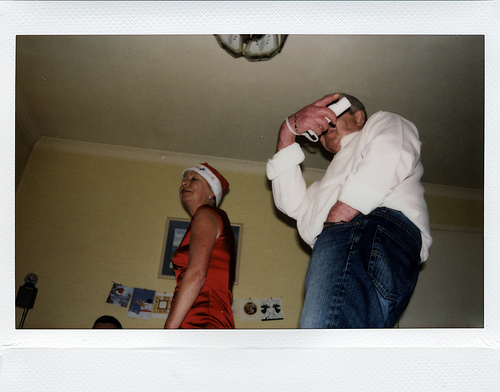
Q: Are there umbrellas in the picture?
A: No, there are no umbrellas.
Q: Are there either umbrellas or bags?
A: No, there are no umbrellas or bags.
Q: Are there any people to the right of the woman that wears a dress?
A: Yes, there are people to the right of the woman.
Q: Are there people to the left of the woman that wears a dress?
A: No, the people are to the right of the woman.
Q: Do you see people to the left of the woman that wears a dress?
A: No, the people are to the right of the woman.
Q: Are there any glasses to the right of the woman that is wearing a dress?
A: No, there are people to the right of the woman.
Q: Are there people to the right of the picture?
A: Yes, there are people to the right of the picture.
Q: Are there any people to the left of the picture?
A: No, the people are to the right of the picture.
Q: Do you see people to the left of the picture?
A: No, the people are to the right of the picture.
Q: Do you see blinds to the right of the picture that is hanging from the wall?
A: No, there are people to the right of the picture.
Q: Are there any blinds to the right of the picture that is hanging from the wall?
A: No, there are people to the right of the picture.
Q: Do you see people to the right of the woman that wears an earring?
A: Yes, there are people to the right of the woman.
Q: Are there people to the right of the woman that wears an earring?
A: Yes, there are people to the right of the woman.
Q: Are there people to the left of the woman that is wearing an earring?
A: No, the people are to the right of the woman.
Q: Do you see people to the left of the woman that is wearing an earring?
A: No, the people are to the right of the woman.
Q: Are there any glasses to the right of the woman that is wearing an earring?
A: No, there are people to the right of the woman.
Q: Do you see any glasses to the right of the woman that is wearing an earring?
A: No, there are people to the right of the woman.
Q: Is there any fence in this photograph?
A: No, there are no fences.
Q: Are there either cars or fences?
A: No, there are no fences or cars.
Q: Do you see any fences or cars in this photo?
A: No, there are no fences or cars.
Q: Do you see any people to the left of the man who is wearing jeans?
A: Yes, there are people to the left of the man.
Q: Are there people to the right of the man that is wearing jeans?
A: No, the people are to the left of the man.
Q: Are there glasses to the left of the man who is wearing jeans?
A: No, there are people to the left of the man.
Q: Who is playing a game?
A: The people are playing a game.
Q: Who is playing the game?
A: The people are playing a game.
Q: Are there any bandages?
A: No, there are no bandages.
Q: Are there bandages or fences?
A: No, there are no bandages or fences.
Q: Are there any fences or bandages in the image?
A: No, there are no bandages or fences.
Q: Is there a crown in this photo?
A: No, there are no crowns.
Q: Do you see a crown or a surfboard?
A: No, there are no crowns or surfboards.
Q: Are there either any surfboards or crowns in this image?
A: No, there are no crowns or surfboards.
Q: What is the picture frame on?
A: The picture frame is on the wall.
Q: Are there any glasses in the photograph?
A: No, there are no glasses.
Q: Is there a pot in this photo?
A: No, there are no pots.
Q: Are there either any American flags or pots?
A: No, there are no pots or American flags.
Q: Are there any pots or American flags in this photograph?
A: No, there are no pots or American flags.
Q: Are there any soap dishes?
A: No, there are no soap dishes.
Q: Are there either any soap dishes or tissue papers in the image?
A: No, there are no soap dishes or tissue papers.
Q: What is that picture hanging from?
A: The picture is hanging from the wall.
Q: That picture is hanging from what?
A: The picture is hanging from the wall.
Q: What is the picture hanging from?
A: The picture is hanging from the wall.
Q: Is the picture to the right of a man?
A: No, the picture is to the left of a man.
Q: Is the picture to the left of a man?
A: Yes, the picture is to the left of a man.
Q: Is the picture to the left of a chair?
A: No, the picture is to the left of a man.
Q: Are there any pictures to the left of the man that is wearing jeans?
A: Yes, there is a picture to the left of the man.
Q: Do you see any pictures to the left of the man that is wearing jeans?
A: Yes, there is a picture to the left of the man.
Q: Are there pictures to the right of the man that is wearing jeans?
A: No, the picture is to the left of the man.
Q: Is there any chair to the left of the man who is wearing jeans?
A: No, there is a picture to the left of the man.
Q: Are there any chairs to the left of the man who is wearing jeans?
A: No, there is a picture to the left of the man.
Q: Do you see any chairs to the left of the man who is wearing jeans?
A: No, there is a picture to the left of the man.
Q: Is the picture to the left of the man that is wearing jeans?
A: Yes, the picture is to the left of the man.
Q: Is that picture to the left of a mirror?
A: No, the picture is to the left of the man.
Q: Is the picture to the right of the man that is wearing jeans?
A: No, the picture is to the left of the man.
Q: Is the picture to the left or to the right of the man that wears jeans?
A: The picture is to the left of the man.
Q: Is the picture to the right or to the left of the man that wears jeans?
A: The picture is to the left of the man.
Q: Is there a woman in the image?
A: Yes, there is a woman.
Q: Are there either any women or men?
A: Yes, there is a woman.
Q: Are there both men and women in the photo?
A: Yes, there are both a woman and a man.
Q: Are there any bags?
A: No, there are no bags.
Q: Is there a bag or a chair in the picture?
A: No, there are no bags or chairs.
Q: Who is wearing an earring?
A: The woman is wearing an earring.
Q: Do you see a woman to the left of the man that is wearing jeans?
A: Yes, there is a woman to the left of the man.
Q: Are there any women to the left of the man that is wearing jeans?
A: Yes, there is a woman to the left of the man.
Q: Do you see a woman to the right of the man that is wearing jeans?
A: No, the woman is to the left of the man.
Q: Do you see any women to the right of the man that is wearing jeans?
A: No, the woman is to the left of the man.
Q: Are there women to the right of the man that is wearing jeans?
A: No, the woman is to the left of the man.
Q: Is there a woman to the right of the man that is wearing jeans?
A: No, the woman is to the left of the man.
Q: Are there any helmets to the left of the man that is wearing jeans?
A: No, there is a woman to the left of the man.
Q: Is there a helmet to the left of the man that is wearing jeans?
A: No, there is a woman to the left of the man.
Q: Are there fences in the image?
A: No, there are no fences.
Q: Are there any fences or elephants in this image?
A: No, there are no fences or elephants.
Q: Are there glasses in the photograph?
A: No, there are no glasses.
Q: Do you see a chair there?
A: No, there are no chairs.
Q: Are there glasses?
A: No, there are no glasses.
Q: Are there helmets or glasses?
A: No, there are no glasses or helmets.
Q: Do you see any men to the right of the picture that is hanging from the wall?
A: Yes, there is a man to the right of the picture.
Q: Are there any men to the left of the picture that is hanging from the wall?
A: No, the man is to the right of the picture.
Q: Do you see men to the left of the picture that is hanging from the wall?
A: No, the man is to the right of the picture.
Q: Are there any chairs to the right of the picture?
A: No, there is a man to the right of the picture.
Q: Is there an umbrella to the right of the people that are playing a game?
A: No, there is a man to the right of the people.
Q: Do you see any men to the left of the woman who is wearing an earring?
A: No, the man is to the right of the woman.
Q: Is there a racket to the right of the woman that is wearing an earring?
A: No, there is a man to the right of the woman.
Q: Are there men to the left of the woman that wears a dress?
A: No, the man is to the right of the woman.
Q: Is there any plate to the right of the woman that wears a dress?
A: No, there is a man to the right of the woman.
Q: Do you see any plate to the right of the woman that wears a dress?
A: No, there is a man to the right of the woman.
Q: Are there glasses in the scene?
A: No, there are no glasses.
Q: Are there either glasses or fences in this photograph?
A: No, there are no glasses or fences.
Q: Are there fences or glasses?
A: No, there are no glasses or fences.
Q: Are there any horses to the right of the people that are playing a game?
A: No, there is a man to the right of the people.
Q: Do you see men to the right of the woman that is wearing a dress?
A: Yes, there is a man to the right of the woman.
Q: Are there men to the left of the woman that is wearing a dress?
A: No, the man is to the right of the woman.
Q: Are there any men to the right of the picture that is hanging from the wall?
A: Yes, there is a man to the right of the picture.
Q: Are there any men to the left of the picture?
A: No, the man is to the right of the picture.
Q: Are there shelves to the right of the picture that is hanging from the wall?
A: No, there is a man to the right of the picture.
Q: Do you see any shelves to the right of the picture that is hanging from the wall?
A: No, there is a man to the right of the picture.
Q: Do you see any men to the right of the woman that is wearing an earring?
A: Yes, there is a man to the right of the woman.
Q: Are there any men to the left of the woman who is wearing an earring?
A: No, the man is to the right of the woman.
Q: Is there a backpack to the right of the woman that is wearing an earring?
A: No, there is a man to the right of the woman.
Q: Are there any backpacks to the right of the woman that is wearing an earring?
A: No, there is a man to the right of the woman.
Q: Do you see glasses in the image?
A: No, there are no glasses.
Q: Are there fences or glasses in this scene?
A: No, there are no glasses or fences.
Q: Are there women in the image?
A: Yes, there is a woman.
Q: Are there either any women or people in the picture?
A: Yes, there is a woman.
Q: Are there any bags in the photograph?
A: No, there are no bags.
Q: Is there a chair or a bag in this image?
A: No, there are no bags or chairs.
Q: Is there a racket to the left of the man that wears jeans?
A: No, there is a woman to the left of the man.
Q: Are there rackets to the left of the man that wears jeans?
A: No, there is a woman to the left of the man.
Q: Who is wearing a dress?
A: The woman is wearing a dress.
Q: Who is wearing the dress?
A: The woman is wearing a dress.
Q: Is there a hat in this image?
A: Yes, there is a hat.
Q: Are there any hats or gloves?
A: Yes, there is a hat.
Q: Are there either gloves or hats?
A: Yes, there is a hat.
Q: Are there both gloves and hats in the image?
A: No, there is a hat but no gloves.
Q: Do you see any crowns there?
A: No, there are no crowns.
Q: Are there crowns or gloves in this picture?
A: No, there are no crowns or gloves.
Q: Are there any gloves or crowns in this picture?
A: No, there are no crowns or gloves.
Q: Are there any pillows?
A: No, there are no pillows.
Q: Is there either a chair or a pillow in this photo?
A: No, there are no pillows or chairs.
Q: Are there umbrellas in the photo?
A: No, there are no umbrellas.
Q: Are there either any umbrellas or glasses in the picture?
A: No, there are no umbrellas or glasses.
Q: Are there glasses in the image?
A: No, there are no glasses.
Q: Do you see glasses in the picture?
A: No, there are no glasses.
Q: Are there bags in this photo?
A: No, there are no bags.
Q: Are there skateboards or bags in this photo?
A: No, there are no bags or skateboards.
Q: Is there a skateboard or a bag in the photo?
A: No, there are no bags or skateboards.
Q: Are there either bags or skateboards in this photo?
A: No, there are no bags or skateboards.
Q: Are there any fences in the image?
A: No, there are no fences.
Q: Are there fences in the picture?
A: No, there are no fences.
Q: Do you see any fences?
A: No, there are no fences.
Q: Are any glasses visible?
A: No, there are no glasses.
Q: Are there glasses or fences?
A: No, there are no glasses or fences.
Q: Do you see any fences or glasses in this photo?
A: No, there are no glasses or fences.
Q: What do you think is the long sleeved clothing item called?
A: The clothing item is a shirt.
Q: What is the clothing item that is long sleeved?
A: The clothing item is a shirt.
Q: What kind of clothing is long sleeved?
A: The clothing is a shirt.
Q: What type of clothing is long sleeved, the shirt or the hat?
A: The shirt is long sleeved.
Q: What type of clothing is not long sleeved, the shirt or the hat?
A: The hat is not long sleeved.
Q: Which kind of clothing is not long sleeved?
A: The clothing is a hat.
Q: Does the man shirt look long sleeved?
A: Yes, the shirt is long sleeved.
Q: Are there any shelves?
A: No, there are no shelves.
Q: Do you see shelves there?
A: No, there are no shelves.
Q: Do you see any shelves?
A: No, there are no shelves.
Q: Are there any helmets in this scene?
A: No, there are no helmets.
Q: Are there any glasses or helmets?
A: No, there are no helmets or glasses.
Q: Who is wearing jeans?
A: The man is wearing jeans.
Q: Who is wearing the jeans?
A: The man is wearing jeans.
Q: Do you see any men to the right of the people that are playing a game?
A: Yes, there is a man to the right of the people.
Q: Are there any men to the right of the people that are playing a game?
A: Yes, there is a man to the right of the people.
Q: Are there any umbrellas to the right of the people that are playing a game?
A: No, there is a man to the right of the people.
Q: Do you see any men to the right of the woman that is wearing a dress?
A: Yes, there is a man to the right of the woman.